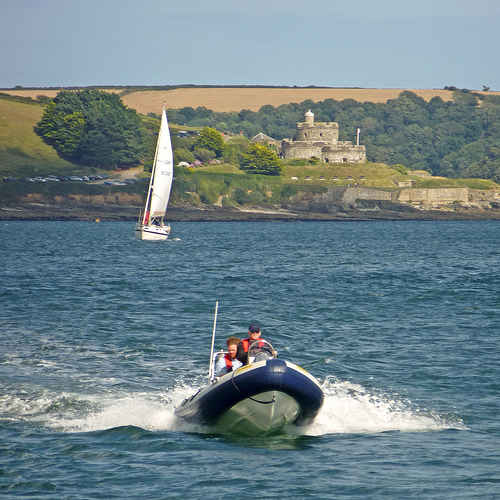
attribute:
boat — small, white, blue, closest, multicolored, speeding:
[113, 263, 370, 452]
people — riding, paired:
[202, 308, 303, 365]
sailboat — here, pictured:
[81, 87, 267, 286]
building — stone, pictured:
[272, 113, 381, 182]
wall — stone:
[394, 191, 473, 231]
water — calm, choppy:
[289, 227, 462, 317]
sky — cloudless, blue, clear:
[32, 14, 497, 64]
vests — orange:
[204, 347, 265, 364]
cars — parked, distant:
[29, 159, 120, 191]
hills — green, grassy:
[4, 100, 59, 186]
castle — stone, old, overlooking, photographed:
[258, 95, 424, 205]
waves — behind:
[40, 379, 166, 456]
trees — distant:
[279, 95, 493, 171]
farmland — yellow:
[137, 82, 379, 112]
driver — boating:
[240, 304, 272, 355]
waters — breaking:
[80, 252, 471, 396]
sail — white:
[145, 122, 192, 203]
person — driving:
[227, 321, 281, 373]